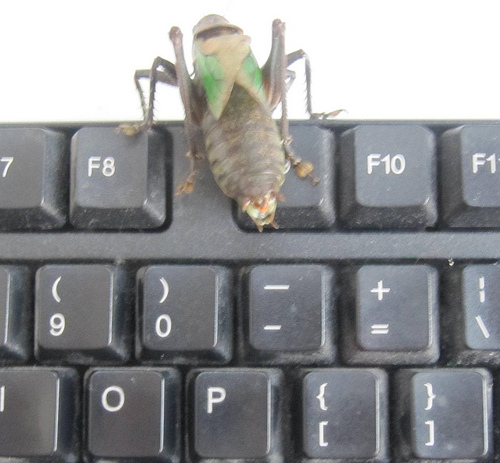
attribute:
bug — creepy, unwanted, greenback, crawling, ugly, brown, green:
[126, 10, 338, 228]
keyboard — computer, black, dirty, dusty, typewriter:
[5, 117, 499, 448]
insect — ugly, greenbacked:
[130, 4, 347, 237]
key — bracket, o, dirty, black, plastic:
[131, 263, 232, 358]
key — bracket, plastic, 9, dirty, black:
[26, 261, 133, 359]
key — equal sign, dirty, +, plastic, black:
[346, 259, 442, 357]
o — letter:
[80, 363, 187, 449]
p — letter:
[193, 363, 283, 454]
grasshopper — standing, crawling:
[119, 1, 345, 243]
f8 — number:
[71, 122, 169, 223]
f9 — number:
[235, 122, 341, 232]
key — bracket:
[302, 367, 389, 454]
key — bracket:
[403, 363, 499, 452]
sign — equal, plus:
[346, 265, 438, 359]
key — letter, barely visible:
[0, 362, 79, 459]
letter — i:
[0, 384, 11, 416]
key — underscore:
[235, 263, 335, 365]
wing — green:
[235, 42, 272, 112]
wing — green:
[196, 32, 249, 117]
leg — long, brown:
[167, 22, 194, 195]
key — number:
[442, 126, 500, 235]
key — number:
[1, 122, 71, 224]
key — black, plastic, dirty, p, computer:
[182, 367, 289, 451]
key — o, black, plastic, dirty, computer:
[76, 362, 185, 458]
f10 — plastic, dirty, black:
[337, 123, 442, 229]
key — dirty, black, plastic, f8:
[62, 124, 174, 234]